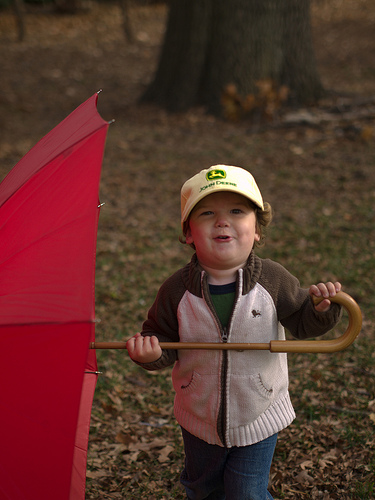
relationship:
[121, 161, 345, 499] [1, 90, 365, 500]
boy holding umbrella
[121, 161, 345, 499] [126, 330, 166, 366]
boy has hand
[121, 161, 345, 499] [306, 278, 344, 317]
boy has hand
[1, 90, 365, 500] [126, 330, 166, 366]
umbrella in hand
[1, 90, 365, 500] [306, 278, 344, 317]
umbrella in hand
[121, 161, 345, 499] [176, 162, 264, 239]
boy wearing hat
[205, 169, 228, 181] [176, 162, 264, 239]
deer on hat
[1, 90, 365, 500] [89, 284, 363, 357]
umbrella has handle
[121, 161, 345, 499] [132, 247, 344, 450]
boy wearing sweater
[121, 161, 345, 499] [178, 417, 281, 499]
boy wearing jeans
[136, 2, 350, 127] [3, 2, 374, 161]
tree trunk in background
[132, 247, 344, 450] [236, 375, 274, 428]
sweater has pocket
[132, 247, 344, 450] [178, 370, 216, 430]
sweater has pocket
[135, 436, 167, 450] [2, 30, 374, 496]
leaf on ground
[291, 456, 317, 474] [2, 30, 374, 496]
leaf on ground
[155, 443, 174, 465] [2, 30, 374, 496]
leaf on ground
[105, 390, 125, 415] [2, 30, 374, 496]
leaf on ground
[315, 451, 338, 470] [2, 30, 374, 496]
leaf on ground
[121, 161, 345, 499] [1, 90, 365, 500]
boy holds umbrella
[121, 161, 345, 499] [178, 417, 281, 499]
boy wears jeans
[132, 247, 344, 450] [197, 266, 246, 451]
sweater has zip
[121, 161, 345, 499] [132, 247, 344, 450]
boy wears sweater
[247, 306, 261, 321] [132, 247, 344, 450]
design on sweater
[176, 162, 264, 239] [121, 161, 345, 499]
hat on boy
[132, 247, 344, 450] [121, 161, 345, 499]
sweater on boy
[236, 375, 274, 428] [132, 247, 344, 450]
pocket on sweater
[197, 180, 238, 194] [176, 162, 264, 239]
text on hat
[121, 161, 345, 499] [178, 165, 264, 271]
boy has head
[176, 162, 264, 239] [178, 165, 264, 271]
hat on head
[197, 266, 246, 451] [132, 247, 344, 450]
zip on sweater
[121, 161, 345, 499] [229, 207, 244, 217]
boy has eye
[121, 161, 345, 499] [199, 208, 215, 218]
boy has eye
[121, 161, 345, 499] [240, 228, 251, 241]
boy has dimple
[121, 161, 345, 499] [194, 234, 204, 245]
boy has dimple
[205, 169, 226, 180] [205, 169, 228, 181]
deer has a deer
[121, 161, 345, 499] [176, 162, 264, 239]
boy wears hat